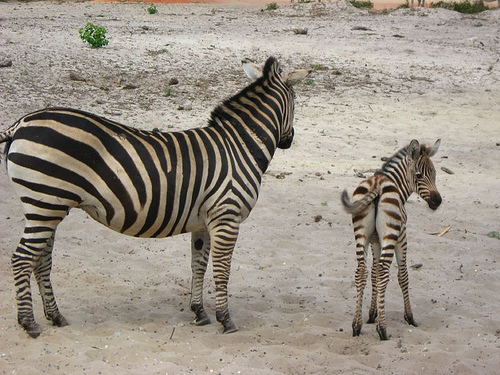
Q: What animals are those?
A: Zebras.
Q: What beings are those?
A: Animals.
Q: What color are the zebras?
A: Black and white.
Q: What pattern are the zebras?
A: Striped.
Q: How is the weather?
A: Warm.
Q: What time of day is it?
A: Day time.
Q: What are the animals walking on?
A: Sand.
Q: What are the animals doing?
A: Walking.